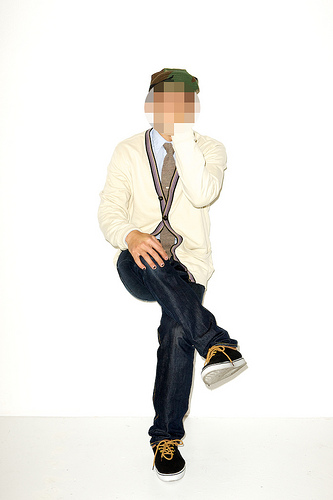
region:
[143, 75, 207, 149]
face is blurred out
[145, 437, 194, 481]
yellow shoelaces on the shoe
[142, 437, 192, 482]
black and white shoe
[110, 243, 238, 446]
dark wash jeans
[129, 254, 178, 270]
nails are painted a dark color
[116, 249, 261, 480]
legs are crossed at the knee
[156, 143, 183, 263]
tie hanging down the torso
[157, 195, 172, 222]
two black buttons on the sweater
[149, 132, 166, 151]
blue collar is down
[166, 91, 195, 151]
hand is lifted to face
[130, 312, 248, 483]
the shoes are black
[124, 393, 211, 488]
the shoes are black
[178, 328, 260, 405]
the shoes are black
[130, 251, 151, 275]
the nail has polish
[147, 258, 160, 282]
the nail has polish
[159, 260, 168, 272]
the nail has polish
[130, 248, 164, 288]
the nail has polish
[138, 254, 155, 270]
the nail has polish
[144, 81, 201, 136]
a mans face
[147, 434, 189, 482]
a black and white shoe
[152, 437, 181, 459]
brown shoe laces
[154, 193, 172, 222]
two black buttons on a brown sweater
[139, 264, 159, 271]
black finger nail polish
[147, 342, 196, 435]
jean pant leg with crease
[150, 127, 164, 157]
pointed collar on a white shirt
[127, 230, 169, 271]
a hand resting on a knee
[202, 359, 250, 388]
the white sole of a shoe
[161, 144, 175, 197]
a brown neck tie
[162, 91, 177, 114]
part of a head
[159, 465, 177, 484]
edge fo a shoe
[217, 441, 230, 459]
part of a shore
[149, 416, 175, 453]
part of a trouser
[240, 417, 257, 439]
part of a floor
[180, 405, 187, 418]
edge of a trouser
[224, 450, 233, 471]
part of a floor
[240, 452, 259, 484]
part of a floor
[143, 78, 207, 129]
blurred out face of person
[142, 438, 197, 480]
black sneakers with yellow laces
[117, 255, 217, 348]
blue jeans on the person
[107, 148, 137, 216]
white shirt on the arm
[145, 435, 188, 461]
yellow laces on the shoe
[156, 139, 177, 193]
brown tie on the person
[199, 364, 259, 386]
white bottoms of the sneaker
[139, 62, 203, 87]
green hat on the person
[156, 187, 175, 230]
buttons on the shirt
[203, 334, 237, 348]
pant legs of the jeans